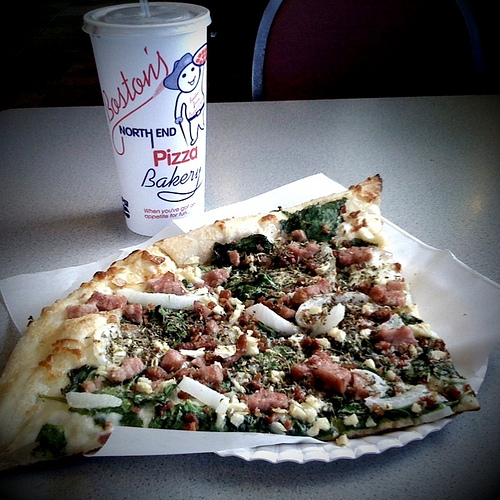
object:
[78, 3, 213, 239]
cup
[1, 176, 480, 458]
pizza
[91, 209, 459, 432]
toppings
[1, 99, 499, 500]
table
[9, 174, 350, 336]
paper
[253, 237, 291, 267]
mushroom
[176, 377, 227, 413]
onion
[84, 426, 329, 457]
napkin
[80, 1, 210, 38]
lid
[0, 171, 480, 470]
crust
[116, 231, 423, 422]
chunk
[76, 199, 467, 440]
in pizza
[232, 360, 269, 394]
cheese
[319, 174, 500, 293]
edge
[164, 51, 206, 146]
man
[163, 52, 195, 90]
hat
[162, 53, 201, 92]
head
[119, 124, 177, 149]
writing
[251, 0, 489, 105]
chair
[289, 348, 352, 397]
meat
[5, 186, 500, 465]
plate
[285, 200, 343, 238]
vegetables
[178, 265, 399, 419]
multiple toppings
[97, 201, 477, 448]
portions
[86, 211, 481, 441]
with toppings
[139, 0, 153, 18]
straw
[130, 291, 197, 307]
onions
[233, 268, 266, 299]
herbs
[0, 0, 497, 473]
meal